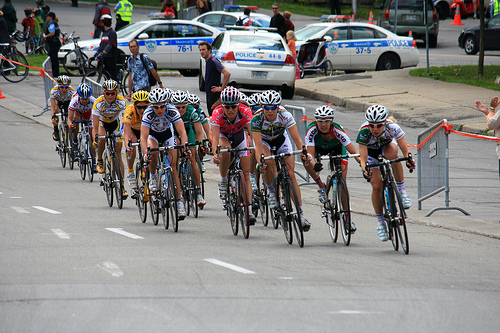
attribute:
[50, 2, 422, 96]
police cars — several, parked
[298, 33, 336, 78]
stroller — for a child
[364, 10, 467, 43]
traffic cones — orange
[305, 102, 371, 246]
racer — on bicycle, on road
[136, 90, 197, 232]
racer — on bicycle, on road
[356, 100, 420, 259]
racer — on road, on bicycle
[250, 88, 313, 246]
racer — on road, on bicycle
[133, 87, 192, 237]
racer — on bicycle, on road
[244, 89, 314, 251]
racer — on road, on bicycle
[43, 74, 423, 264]
several bicyclists — riding the roadway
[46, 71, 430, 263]
multiple bicyclists — riding the roadway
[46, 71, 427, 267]
alert bicyclists — riding the roadway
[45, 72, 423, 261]
bicyclists group — on the road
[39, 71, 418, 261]
several cyclists — in a line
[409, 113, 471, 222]
barrier — metal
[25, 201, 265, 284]
lines — white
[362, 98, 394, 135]
bicycle helmet — white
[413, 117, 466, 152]
tape — orange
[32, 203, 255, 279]
markings — white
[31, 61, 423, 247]
cyclists — racing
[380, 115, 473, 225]
barricade — broken, metal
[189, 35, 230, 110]
man — race-watching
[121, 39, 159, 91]
man — race-watching